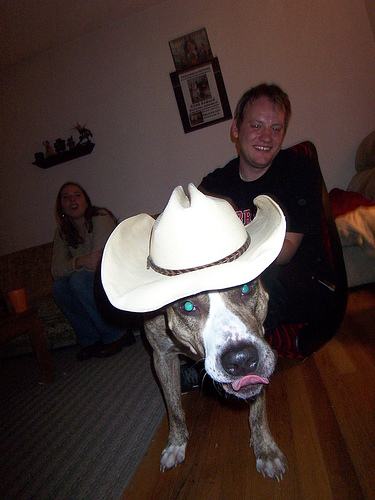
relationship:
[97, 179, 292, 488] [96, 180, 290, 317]
dog wearing cowboy hat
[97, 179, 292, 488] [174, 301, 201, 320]
dog has eye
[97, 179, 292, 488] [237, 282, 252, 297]
dog has eye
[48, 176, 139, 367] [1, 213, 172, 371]
girl on couch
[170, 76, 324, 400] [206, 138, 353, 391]
boy in gaming chair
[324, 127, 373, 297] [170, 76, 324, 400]
recliner chair behind boy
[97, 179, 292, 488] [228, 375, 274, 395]
dog has tongue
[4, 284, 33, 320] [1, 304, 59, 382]
cup on coffee table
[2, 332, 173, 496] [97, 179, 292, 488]
rug next to dog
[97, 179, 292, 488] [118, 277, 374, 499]
dog on floor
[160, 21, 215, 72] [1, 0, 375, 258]
picture on wall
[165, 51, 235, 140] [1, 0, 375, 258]
picture on wall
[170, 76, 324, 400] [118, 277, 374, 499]
boy sitting on floor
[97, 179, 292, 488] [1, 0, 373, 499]
dog in living room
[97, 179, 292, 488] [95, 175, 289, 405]
dog has head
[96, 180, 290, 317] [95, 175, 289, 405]
cowboy hat on head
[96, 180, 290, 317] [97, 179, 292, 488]
cowboy hat on dog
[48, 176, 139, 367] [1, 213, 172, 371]
girl sitting on couch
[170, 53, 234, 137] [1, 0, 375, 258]
newspaper article on wall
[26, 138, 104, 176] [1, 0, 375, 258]
shelf on wall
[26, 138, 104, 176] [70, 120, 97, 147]
shelf has knick knack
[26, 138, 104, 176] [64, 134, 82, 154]
shelf has knick knack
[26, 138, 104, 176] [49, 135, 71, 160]
shelf has knick knack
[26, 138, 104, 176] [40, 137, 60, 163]
shelf has knick knack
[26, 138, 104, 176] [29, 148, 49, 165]
shelf has knick knack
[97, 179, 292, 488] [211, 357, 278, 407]
dog has mouth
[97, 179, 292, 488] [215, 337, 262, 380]
dog has nose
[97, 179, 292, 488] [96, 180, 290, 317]
dog has cowboy hat